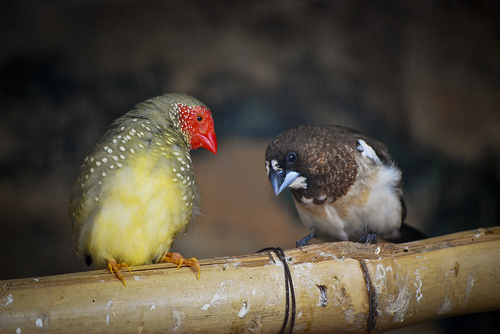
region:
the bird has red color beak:
[70, 89, 218, 284]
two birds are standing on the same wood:
[6, 92, 498, 329]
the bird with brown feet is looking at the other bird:
[66, 91, 426, 286]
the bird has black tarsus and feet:
[265, 124, 427, 251]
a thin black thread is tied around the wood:
[10, 230, 496, 332]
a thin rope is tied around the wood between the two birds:
[9, 92, 494, 329]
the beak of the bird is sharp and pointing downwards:
[263, 124, 429, 251]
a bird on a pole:
[229, 97, 417, 315]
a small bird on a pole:
[282, 113, 476, 328]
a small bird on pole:
[82, 92, 261, 324]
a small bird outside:
[267, 127, 432, 272]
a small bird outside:
[7, 56, 283, 332]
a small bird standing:
[268, 115, 370, 227]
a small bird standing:
[72, 66, 228, 316]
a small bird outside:
[99, 58, 251, 326]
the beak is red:
[174, 88, 222, 159]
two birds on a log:
[41, 81, 426, 309]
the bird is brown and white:
[251, 115, 418, 250]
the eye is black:
[283, 145, 298, 166]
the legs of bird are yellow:
[103, 249, 203, 285]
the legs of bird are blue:
[290, 224, 380, 253]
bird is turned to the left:
[58, 78, 238, 285]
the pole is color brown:
[3, 226, 499, 331]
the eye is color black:
[191, 111, 206, 126]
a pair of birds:
[59, 52, 424, 278]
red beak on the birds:
[189, 117, 226, 157]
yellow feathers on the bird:
[99, 147, 180, 279]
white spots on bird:
[63, 109, 202, 240]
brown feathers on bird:
[264, 115, 356, 192]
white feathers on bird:
[311, 201, 406, 236]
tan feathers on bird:
[302, 178, 374, 214]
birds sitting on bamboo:
[0, 67, 499, 328]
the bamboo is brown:
[0, 217, 499, 332]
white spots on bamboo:
[0, 215, 498, 332]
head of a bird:
[242, 108, 339, 221]